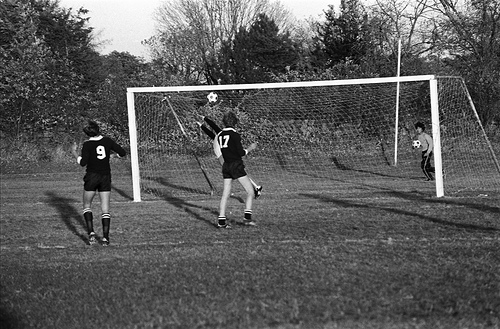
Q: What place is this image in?
A: It is at the field.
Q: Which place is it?
A: It is a field.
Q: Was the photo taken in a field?
A: Yes, it was taken in a field.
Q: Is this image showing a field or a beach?
A: It is showing a field.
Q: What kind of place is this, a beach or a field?
A: It is a field.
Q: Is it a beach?
A: No, it is a field.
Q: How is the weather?
A: It is clear.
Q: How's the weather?
A: It is clear.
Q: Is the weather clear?
A: Yes, it is clear.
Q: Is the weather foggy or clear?
A: It is clear.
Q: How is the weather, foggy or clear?
A: It is clear.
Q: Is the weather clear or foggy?
A: It is clear.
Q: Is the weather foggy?
A: No, it is clear.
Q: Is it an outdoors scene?
A: Yes, it is outdoors.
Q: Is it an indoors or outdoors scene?
A: It is outdoors.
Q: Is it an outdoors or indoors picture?
A: It is outdoors.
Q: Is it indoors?
A: No, it is outdoors.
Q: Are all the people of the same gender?
A: No, they are both male and female.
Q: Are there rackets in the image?
A: No, there are no rackets.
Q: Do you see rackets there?
A: No, there are no rackets.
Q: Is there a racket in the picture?
A: No, there are no rackets.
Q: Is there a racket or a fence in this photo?
A: No, there are no rackets or fences.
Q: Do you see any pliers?
A: No, there are no pliers.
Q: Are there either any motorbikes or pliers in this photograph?
A: No, there are no pliers or motorbikes.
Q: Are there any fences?
A: No, there are no fences.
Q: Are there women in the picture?
A: Yes, there is a woman.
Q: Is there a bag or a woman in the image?
A: Yes, there is a woman.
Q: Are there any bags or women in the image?
A: Yes, there is a woman.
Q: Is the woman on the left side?
A: Yes, the woman is on the left of the image.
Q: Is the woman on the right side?
A: No, the woman is on the left of the image.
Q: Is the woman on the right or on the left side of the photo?
A: The woman is on the left of the image.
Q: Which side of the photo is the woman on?
A: The woman is on the left of the image.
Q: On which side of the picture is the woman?
A: The woman is on the left of the image.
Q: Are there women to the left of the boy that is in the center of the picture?
A: Yes, there is a woman to the left of the boy.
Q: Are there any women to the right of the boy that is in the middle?
A: No, the woman is to the left of the boy.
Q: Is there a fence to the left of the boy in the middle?
A: No, there is a woman to the left of the boy.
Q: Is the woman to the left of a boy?
A: Yes, the woman is to the left of a boy.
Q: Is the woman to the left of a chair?
A: No, the woman is to the left of a boy.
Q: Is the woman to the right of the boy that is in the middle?
A: No, the woman is to the left of the boy.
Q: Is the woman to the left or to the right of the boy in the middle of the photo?
A: The woman is to the left of the boy.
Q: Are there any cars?
A: No, there are no cars.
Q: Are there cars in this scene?
A: No, there are no cars.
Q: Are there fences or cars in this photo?
A: No, there are no cars or fences.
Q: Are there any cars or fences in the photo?
A: No, there are no cars or fences.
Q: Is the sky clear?
A: Yes, the sky is clear.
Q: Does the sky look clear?
A: Yes, the sky is clear.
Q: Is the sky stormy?
A: No, the sky is clear.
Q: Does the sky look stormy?
A: No, the sky is clear.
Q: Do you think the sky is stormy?
A: No, the sky is clear.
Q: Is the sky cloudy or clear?
A: The sky is clear.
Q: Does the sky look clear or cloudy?
A: The sky is clear.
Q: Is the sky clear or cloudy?
A: The sky is clear.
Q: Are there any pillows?
A: No, there are no pillows.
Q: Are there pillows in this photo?
A: No, there are no pillows.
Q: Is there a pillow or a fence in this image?
A: No, there are no pillows or fences.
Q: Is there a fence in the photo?
A: No, there are no fences.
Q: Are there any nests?
A: No, there are no nests.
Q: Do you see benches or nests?
A: No, there are no nests or benches.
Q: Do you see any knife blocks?
A: No, there are no knife blocks.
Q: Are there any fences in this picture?
A: No, there are no fences.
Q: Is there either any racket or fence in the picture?
A: No, there are no fences or rackets.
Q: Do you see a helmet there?
A: No, there are no helmets.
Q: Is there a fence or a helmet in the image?
A: No, there are no helmets or fences.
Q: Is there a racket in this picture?
A: No, there are no rackets.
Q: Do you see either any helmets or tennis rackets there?
A: No, there are no tennis rackets or helmets.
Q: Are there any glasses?
A: No, there are no glasses.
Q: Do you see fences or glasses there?
A: No, there are no glasses or fences.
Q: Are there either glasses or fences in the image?
A: No, there are no glasses or fences.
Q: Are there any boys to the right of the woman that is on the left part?
A: Yes, there is a boy to the right of the woman.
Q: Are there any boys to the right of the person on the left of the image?
A: Yes, there is a boy to the right of the woman.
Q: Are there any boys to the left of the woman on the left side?
A: No, the boy is to the right of the woman.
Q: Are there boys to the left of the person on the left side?
A: No, the boy is to the right of the woman.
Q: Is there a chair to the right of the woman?
A: No, there is a boy to the right of the woman.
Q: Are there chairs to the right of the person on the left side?
A: No, there is a boy to the right of the woman.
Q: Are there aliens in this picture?
A: No, there are no aliens.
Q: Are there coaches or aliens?
A: No, there are no aliens or coaches.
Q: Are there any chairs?
A: No, there are no chairs.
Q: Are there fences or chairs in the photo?
A: No, there are no chairs or fences.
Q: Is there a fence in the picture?
A: No, there are no fences.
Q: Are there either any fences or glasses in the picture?
A: No, there are no fences or glasses.